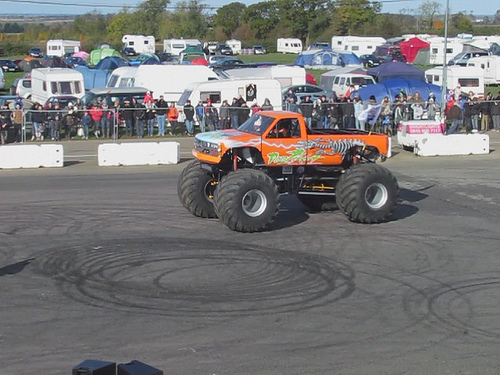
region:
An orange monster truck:
[188, 91, 416, 232]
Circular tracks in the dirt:
[34, 223, 421, 351]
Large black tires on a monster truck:
[211, 163, 284, 244]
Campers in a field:
[163, 25, 318, 62]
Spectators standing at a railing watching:
[41, 93, 215, 136]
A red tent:
[395, 35, 429, 66]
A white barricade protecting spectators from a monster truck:
[94, 130, 192, 171]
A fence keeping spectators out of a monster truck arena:
[21, 107, 120, 155]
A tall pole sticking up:
[433, 7, 464, 146]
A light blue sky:
[8, 3, 65, 13]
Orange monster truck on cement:
[171, 95, 388, 198]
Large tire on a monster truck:
[215, 166, 290, 261]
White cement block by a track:
[83, 139, 199, 182]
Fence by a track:
[20, 111, 167, 136]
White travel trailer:
[31, 65, 99, 110]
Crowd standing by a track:
[106, 93, 311, 138]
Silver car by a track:
[288, 83, 338, 108]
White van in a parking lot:
[321, 65, 403, 124]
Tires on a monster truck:
[158, 158, 328, 250]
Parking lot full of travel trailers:
[93, 40, 440, 174]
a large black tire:
[209, 169, 291, 234]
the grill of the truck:
[190, 131, 225, 165]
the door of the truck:
[259, 111, 302, 171]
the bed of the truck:
[302, 124, 397, 181]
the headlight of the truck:
[205, 138, 220, 159]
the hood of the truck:
[196, 123, 258, 148]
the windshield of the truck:
[234, 106, 275, 138]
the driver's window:
[260, 116, 302, 144]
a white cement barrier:
[94, 136, 182, 167]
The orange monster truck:
[177, 103, 399, 230]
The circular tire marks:
[27, 225, 497, 349]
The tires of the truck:
[175, 156, 400, 230]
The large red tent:
[398, 35, 430, 62]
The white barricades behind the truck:
[0, 132, 493, 170]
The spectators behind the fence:
[1, 88, 498, 140]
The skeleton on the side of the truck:
[293, 138, 368, 158]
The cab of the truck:
[246, 108, 308, 163]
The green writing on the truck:
[265, 147, 322, 168]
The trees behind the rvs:
[3, 1, 480, 56]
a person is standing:
[1, 100, 12, 137]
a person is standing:
[12, 102, 23, 141]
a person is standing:
[29, 102, 46, 132]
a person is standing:
[50, 113, 67, 141]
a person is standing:
[46, 102, 57, 132]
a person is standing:
[63, 101, 80, 130]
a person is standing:
[86, 98, 104, 131]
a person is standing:
[121, 97, 135, 136]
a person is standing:
[135, 97, 147, 130]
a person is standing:
[143, 97, 159, 131]